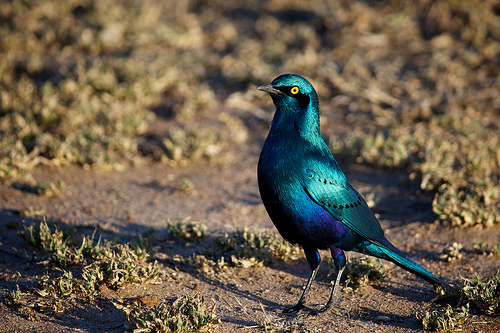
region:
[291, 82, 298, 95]
A small yellow bird's eye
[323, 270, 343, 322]
A small grey bird's feet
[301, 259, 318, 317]
A small grey bird's feet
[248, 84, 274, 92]
A small sharp beak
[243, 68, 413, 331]
A beautiful shiny purple bird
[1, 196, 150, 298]
Dry scartted grass ground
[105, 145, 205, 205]
Dry scartted grass ground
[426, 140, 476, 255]
Dry scartted grass ground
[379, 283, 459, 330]
Dry scartted grass ground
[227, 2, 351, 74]
Dry scartted grass ground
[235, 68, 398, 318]
the bird on the ground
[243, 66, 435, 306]
the bird is shiny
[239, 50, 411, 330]
the bird is blue green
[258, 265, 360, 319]
the feet of the bird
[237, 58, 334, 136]
the head of the bird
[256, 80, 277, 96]
the beak of the bird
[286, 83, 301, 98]
the eye of the bird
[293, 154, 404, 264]
the wing of the bird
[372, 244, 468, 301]
the tail of the bird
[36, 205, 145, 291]
the grass on the ground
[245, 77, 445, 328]
this is a bird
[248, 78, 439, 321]
the bird is on the ground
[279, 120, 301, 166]
the feathers are shiny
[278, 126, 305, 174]
the feathers are blue in color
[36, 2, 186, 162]
this is the grass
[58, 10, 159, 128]
the grass is green in color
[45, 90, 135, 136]
the grass is short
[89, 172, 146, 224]
this is the ground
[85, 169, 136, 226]
the ground is sandy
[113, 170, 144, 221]
the sand is brown in color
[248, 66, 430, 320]
Bird is standing in ground.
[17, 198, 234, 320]
Shadow falls on ground.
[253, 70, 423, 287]
bird is blue color.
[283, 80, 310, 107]
Eyes are yellow color.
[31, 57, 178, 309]
Patches of grass are in ground.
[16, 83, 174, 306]
grass are green and brown color.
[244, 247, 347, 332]
Legs are black color.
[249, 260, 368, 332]
Two legs for bird.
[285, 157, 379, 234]
Black dots in the feather.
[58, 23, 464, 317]
Day time picture.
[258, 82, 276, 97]
the beak on the bird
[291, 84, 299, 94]
the eye on the bird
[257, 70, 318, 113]
the head on the bird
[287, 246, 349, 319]
the two legs on the bird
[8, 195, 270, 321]
the shadow on the ground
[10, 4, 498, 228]
patches of grass on the ground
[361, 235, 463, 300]
the birds tail feather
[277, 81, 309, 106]
the black markings on the bird's head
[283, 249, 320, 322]
the right leg on the bird